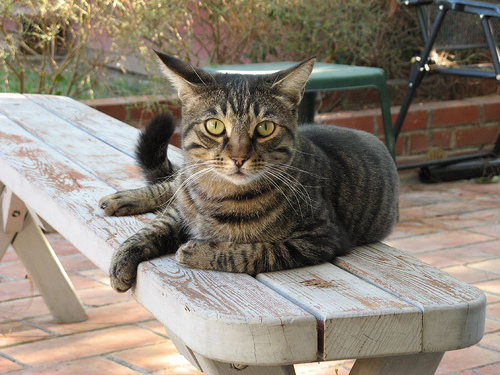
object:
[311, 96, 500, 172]
wall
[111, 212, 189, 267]
leg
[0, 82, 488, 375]
bench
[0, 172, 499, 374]
patio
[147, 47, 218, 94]
ear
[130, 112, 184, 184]
tail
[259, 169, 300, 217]
whiskers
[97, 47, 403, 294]
cat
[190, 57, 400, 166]
table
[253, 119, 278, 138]
eye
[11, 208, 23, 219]
bolt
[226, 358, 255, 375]
bolt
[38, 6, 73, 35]
leaf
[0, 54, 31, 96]
stem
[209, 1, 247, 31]
leaf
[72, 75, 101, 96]
leaf